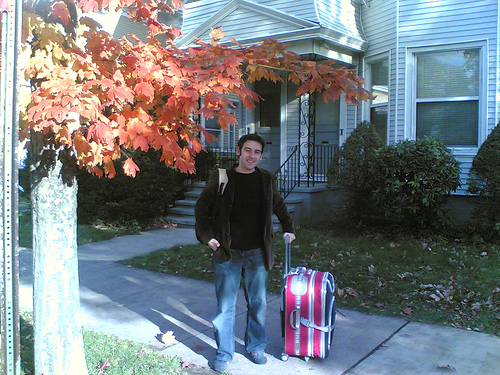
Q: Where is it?
A: This is at the sidewalk.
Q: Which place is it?
A: It is a sidewalk.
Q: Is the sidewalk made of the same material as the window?
A: No, the sidewalk is made of concrete and the window is made of glass.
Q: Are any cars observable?
A: No, there are no cars.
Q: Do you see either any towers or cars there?
A: No, there are no cars or towers.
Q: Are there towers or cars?
A: No, there are no cars or towers.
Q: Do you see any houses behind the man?
A: Yes, there is a house behind the man.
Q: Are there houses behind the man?
A: Yes, there is a house behind the man.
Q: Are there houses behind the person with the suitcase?
A: Yes, there is a house behind the man.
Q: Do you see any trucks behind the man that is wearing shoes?
A: No, there is a house behind the man.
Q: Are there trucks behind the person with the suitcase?
A: No, there is a house behind the man.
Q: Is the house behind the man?
A: Yes, the house is behind the man.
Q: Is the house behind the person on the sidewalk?
A: Yes, the house is behind the man.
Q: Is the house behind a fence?
A: No, the house is behind the man.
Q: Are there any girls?
A: No, there are no girls.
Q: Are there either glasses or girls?
A: No, there are no girls or glasses.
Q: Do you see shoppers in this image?
A: No, there are no shoppers.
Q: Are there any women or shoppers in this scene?
A: No, there are no shoppers or women.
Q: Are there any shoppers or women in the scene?
A: No, there are no shoppers or women.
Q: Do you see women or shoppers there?
A: No, there are no shoppers or women.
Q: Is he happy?
A: Yes, the man is happy.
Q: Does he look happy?
A: Yes, the man is happy.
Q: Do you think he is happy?
A: Yes, the man is happy.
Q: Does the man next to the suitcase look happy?
A: Yes, the man is happy.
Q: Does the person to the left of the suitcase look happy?
A: Yes, the man is happy.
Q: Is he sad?
A: No, the man is happy.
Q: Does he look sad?
A: No, the man is happy.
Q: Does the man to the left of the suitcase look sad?
A: No, the man is happy.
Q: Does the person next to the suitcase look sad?
A: No, the man is happy.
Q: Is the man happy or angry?
A: The man is happy.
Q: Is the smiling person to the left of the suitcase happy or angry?
A: The man is happy.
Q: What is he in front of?
A: The man is in front of the house.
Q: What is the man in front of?
A: The man is in front of the house.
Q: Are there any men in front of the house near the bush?
A: Yes, there is a man in front of the house.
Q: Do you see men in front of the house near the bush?
A: Yes, there is a man in front of the house.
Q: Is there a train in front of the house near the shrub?
A: No, there is a man in front of the house.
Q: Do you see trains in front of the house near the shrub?
A: No, there is a man in front of the house.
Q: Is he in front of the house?
A: Yes, the man is in front of the house.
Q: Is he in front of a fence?
A: No, the man is in front of the house.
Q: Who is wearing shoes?
A: The man is wearing shoes.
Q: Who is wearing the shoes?
A: The man is wearing shoes.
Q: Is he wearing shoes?
A: Yes, the man is wearing shoes.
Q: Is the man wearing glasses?
A: No, the man is wearing shoes.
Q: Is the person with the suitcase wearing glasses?
A: No, the man is wearing shoes.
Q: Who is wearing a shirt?
A: The man is wearing a shirt.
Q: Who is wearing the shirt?
A: The man is wearing a shirt.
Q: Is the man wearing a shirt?
A: Yes, the man is wearing a shirt.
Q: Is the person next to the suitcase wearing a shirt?
A: Yes, the man is wearing a shirt.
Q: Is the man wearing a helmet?
A: No, the man is wearing a shirt.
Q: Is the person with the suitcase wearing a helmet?
A: No, the man is wearing a shirt.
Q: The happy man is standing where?
A: The man is standing on the side walk.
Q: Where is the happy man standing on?
A: The man is standing on the side walk.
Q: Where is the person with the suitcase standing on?
A: The man is standing on the side walk.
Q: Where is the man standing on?
A: The man is standing on the side walk.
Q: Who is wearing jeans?
A: The man is wearing jeans.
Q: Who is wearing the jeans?
A: The man is wearing jeans.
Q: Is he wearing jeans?
A: Yes, the man is wearing jeans.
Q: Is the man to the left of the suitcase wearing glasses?
A: No, the man is wearing jeans.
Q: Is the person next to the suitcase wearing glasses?
A: No, the man is wearing jeans.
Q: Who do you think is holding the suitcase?
A: The man is holding the suitcase.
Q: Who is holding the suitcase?
A: The man is holding the suitcase.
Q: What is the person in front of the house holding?
A: The man is holding the suitcase.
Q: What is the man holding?
A: The man is holding the suitcase.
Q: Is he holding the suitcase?
A: Yes, the man is holding the suitcase.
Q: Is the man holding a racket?
A: No, the man is holding the suitcase.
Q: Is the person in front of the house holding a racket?
A: No, the man is holding the suitcase.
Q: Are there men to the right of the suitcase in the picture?
A: No, the man is to the left of the suitcase.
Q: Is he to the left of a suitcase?
A: Yes, the man is to the left of a suitcase.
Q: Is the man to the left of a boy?
A: No, the man is to the left of a suitcase.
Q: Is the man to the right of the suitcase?
A: No, the man is to the left of the suitcase.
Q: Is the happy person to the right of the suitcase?
A: No, the man is to the left of the suitcase.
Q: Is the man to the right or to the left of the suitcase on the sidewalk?
A: The man is to the left of the suitcase.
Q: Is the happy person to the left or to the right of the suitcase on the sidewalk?
A: The man is to the left of the suitcase.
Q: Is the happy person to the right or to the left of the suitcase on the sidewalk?
A: The man is to the left of the suitcase.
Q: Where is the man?
A: The man is on the side walk.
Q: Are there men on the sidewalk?
A: Yes, there is a man on the sidewalk.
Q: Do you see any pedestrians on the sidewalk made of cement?
A: No, there is a man on the side walk.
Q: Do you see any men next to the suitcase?
A: Yes, there is a man next to the suitcase.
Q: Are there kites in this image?
A: No, there are no kites.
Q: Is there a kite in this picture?
A: No, there are no kites.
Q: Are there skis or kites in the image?
A: No, there are no kites or skis.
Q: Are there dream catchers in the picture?
A: No, there are no dream catchers.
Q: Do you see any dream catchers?
A: No, there are no dream catchers.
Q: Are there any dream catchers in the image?
A: No, there are no dream catchers.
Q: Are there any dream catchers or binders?
A: No, there are no dream catchers or binders.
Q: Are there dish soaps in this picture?
A: No, there are no dish soaps.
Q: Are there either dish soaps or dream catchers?
A: No, there are no dish soaps or dream catchers.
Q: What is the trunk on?
A: The trunk is on the tree.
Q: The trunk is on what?
A: The trunk is on the tree.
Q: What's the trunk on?
A: The trunk is on the tree.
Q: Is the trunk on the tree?
A: Yes, the trunk is on the tree.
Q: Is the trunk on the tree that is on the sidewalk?
A: Yes, the trunk is on the tree.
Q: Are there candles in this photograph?
A: No, there are no candles.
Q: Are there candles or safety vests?
A: No, there are no candles or safety vests.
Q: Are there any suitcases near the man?
A: Yes, there is a suitcase near the man.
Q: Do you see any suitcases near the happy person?
A: Yes, there is a suitcase near the man.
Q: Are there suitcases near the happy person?
A: Yes, there is a suitcase near the man.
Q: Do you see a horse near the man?
A: No, there is a suitcase near the man.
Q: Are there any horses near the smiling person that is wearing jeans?
A: No, there is a suitcase near the man.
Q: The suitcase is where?
A: The suitcase is on the side walk.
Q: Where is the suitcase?
A: The suitcase is on the side walk.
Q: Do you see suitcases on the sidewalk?
A: Yes, there is a suitcase on the sidewalk.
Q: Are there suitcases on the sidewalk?
A: Yes, there is a suitcase on the sidewalk.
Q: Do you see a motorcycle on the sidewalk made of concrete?
A: No, there is a suitcase on the sidewalk.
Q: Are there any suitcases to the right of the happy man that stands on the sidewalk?
A: Yes, there is a suitcase to the right of the man.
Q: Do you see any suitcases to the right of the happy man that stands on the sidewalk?
A: Yes, there is a suitcase to the right of the man.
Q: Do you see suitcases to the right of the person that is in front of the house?
A: Yes, there is a suitcase to the right of the man.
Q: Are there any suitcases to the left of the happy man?
A: No, the suitcase is to the right of the man.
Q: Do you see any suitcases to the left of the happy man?
A: No, the suitcase is to the right of the man.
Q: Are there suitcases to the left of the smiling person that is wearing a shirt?
A: No, the suitcase is to the right of the man.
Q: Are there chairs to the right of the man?
A: No, there is a suitcase to the right of the man.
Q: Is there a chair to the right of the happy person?
A: No, there is a suitcase to the right of the man.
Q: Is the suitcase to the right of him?
A: Yes, the suitcase is to the right of the man.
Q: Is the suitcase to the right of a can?
A: No, the suitcase is to the right of the man.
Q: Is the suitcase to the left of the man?
A: No, the suitcase is to the right of the man.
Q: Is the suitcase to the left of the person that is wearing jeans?
A: No, the suitcase is to the right of the man.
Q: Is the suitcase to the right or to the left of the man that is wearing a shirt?
A: The suitcase is to the right of the man.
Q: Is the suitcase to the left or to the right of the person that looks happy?
A: The suitcase is to the right of the man.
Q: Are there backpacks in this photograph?
A: Yes, there is a backpack.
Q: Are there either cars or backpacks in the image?
A: Yes, there is a backpack.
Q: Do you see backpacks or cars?
A: Yes, there is a backpack.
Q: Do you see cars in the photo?
A: No, there are no cars.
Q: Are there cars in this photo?
A: No, there are no cars.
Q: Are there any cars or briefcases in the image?
A: No, there are no cars or briefcases.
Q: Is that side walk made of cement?
A: Yes, the side walk is made of cement.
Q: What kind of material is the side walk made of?
A: The side walk is made of concrete.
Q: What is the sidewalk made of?
A: The side walk is made of concrete.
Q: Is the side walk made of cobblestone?
A: No, the side walk is made of cement.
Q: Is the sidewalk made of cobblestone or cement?
A: The sidewalk is made of cement.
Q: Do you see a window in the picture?
A: Yes, there is a window.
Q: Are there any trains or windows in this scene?
A: Yes, there is a window.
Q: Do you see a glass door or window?
A: Yes, there is a glass window.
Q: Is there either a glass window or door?
A: Yes, there is a glass window.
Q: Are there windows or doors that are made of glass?
A: Yes, the window is made of glass.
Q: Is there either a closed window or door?
A: Yes, there is a closed window.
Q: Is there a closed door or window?
A: Yes, there is a closed window.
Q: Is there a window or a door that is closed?
A: Yes, the window is closed.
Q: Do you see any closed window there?
A: Yes, there is a closed window.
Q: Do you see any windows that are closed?
A: Yes, there is a window that is closed.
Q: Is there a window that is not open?
A: Yes, there is an closed window.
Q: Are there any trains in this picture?
A: No, there are no trains.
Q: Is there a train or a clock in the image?
A: No, there are no trains or clocks.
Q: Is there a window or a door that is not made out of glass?
A: No, there is a window but it is made of glass.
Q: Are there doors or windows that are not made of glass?
A: No, there is a window but it is made of glass.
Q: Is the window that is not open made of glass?
A: Yes, the window is made of glass.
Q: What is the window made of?
A: The window is made of glass.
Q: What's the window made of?
A: The window is made of glass.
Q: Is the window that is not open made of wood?
A: No, the window is made of glass.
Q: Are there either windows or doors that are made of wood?
A: No, there is a window but it is made of glass.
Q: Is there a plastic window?
A: No, there is a window but it is made of glass.